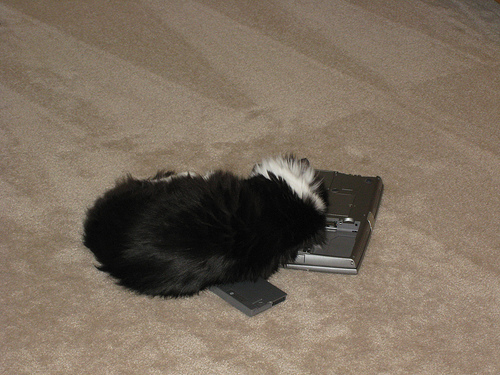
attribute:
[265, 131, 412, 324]
laptop — closed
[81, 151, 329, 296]
black cat — white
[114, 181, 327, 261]
cat — waiting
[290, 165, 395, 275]
laptop — off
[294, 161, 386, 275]
laptop — grey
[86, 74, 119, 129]
carpet — tan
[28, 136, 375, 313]
cat — waiting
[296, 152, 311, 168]
nose — black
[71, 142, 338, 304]
dog — black, white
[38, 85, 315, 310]
cat — black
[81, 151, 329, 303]
cat — sleeping, resting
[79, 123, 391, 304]
cat — white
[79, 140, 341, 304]
cat — napping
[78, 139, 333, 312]
dog — white, black, fluffy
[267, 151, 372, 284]
laptop — upside down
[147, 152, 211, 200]
leg — white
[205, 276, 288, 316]
pack — battery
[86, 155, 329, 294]
dog — sleeping, dead, black, white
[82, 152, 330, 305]
fur — black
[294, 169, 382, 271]
device — electronic